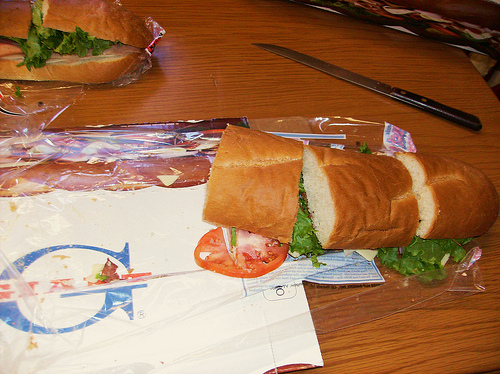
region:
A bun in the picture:
[200, 147, 474, 247]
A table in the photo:
[345, 304, 445, 344]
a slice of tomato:
[200, 226, 290, 279]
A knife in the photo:
[255, 34, 493, 149]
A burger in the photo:
[15, 12, 146, 92]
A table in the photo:
[210, 57, 304, 123]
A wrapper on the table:
[44, 184, 189, 310]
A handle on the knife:
[398, 82, 488, 134]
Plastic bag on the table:
[354, 287, 433, 323]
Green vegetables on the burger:
[383, 237, 460, 281]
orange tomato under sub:
[196, 205, 287, 297]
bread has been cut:
[200, 130, 496, 263]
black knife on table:
[282, 42, 480, 169]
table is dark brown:
[122, 34, 459, 166]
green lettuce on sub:
[268, 147, 488, 319]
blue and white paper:
[191, 250, 368, 285]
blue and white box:
[42, 140, 255, 371]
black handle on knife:
[323, 82, 493, 147]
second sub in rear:
[3, 30, 183, 107]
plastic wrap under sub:
[2, 32, 169, 171]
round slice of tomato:
[196, 228, 287, 276]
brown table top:
[376, 330, 490, 363]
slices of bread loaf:
[306, 145, 497, 242]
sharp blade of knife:
[251, 37, 390, 92]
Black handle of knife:
[396, 86, 483, 129]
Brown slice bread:
[204, 125, 305, 225]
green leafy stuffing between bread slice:
[0, 5, 144, 82]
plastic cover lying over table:
[56, 126, 182, 319]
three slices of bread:
[214, 126, 498, 246]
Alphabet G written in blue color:
[1, 242, 133, 329]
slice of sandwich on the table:
[179, 110, 319, 284]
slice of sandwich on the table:
[292, 131, 425, 265]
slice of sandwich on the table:
[386, 148, 497, 275]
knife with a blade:
[252, 37, 482, 136]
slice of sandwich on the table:
[0, 0, 175, 89]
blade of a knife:
[240, 36, 390, 102]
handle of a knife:
[389, 80, 485, 133]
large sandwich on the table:
[175, 93, 499, 300]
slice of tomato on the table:
[193, 227, 289, 279]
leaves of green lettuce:
[372, 232, 473, 289]